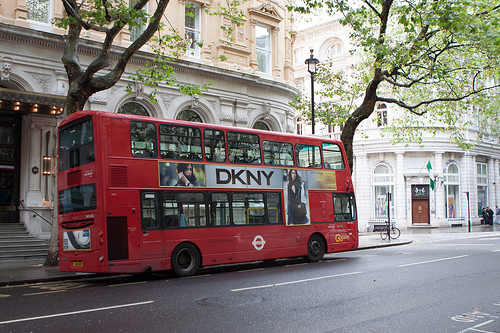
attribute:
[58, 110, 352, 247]
bus — painted red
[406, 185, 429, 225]
door — wooden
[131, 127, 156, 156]
window — glass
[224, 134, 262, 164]
window — glass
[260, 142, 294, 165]
window — glass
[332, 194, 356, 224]
window — glass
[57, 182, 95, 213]
window — glass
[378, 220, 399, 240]
bike — black, pedal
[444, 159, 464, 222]
window — rounded, glass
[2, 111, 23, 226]
door — tall, brown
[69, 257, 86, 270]
plate — small, yellow, license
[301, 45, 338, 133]
lamp post — black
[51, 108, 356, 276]
bus — red, double decker, double, decker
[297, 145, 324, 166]
window — glass